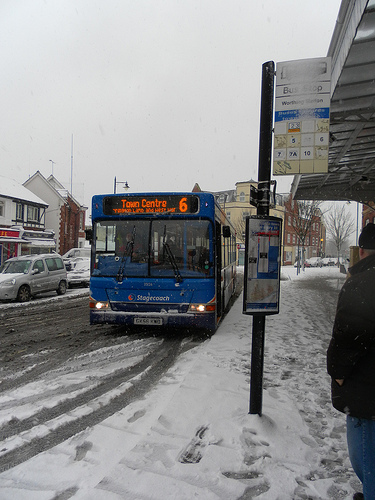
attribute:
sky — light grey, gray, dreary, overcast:
[1, 2, 374, 241]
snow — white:
[1, 267, 360, 498]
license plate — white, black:
[132, 315, 162, 327]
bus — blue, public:
[86, 191, 241, 334]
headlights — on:
[192, 301, 205, 315]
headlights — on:
[90, 302, 106, 312]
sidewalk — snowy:
[88, 275, 373, 499]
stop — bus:
[87, 1, 373, 500]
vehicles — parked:
[1, 251, 69, 308]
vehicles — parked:
[66, 256, 93, 288]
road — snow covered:
[3, 255, 251, 497]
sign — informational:
[235, 213, 288, 324]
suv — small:
[56, 242, 88, 276]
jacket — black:
[324, 257, 375, 420]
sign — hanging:
[270, 57, 333, 179]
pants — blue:
[342, 409, 374, 500]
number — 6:
[178, 195, 189, 213]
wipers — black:
[161, 240, 185, 283]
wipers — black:
[114, 240, 134, 278]